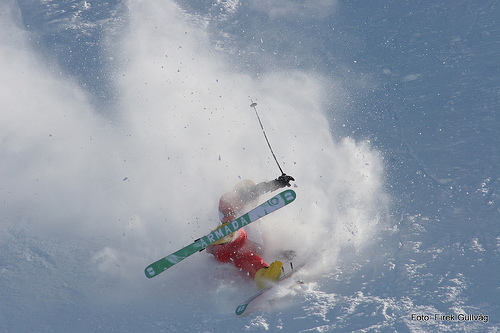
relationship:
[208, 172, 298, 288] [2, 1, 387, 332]
man behind snow splash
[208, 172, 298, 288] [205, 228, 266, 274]
man has pants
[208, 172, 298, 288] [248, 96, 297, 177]
man has pole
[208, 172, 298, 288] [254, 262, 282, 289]
man has shoe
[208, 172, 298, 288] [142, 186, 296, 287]
man has ski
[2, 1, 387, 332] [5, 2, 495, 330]
snow splash above field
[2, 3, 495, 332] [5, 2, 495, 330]
snow covering field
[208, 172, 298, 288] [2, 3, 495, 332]
man skiing in snow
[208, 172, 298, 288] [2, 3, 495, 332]
man skiing on snow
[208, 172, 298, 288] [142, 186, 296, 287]
man riding on ski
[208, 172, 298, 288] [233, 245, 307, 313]
man riding on ski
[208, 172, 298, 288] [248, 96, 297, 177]
man holding pole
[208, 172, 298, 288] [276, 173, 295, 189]
man has hand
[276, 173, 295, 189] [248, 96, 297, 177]
hand has pole